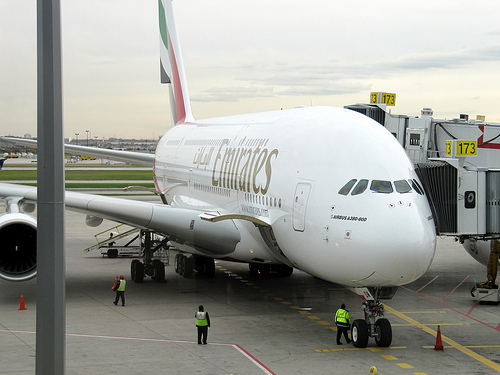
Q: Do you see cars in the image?
A: No, there are no cars.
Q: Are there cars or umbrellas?
A: No, there are no cars or umbrellas.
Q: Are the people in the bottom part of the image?
A: Yes, the people are in the bottom of the image.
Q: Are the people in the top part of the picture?
A: No, the people are in the bottom of the image.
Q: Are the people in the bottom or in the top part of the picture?
A: The people are in the bottom of the image.